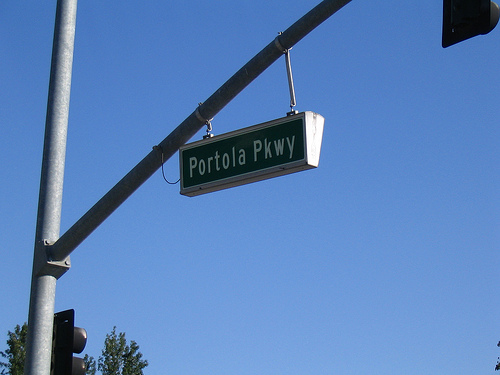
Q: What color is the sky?
A: Blue.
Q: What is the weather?
A: Sunny.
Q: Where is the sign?
A: Hanging on the pole.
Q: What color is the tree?
A: Green.